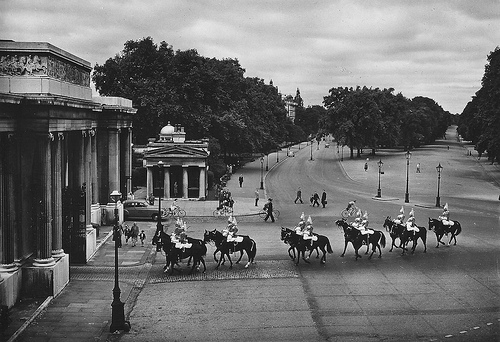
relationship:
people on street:
[287, 201, 454, 238] [16, 134, 498, 340]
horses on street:
[154, 216, 461, 271] [16, 134, 498, 340]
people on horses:
[287, 201, 454, 238] [154, 216, 461, 271]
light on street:
[374, 160, 384, 198] [324, 112, 497, 272]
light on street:
[402, 147, 412, 203] [324, 112, 497, 272]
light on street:
[432, 161, 443, 208] [324, 112, 497, 272]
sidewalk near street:
[14, 218, 163, 340] [189, 286, 438, 326]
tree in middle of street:
[93, 36, 500, 187] [181, 281, 423, 340]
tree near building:
[93, 36, 500, 187] [0, 27, 152, 272]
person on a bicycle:
[264, 199, 274, 219] [164, 207, 187, 218]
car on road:
[123, 199, 167, 221] [340, 268, 430, 324]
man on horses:
[170, 215, 189, 245] [269, 218, 337, 268]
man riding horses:
[170, 215, 189, 245] [269, 218, 337, 268]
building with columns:
[1, 38, 134, 308] [4, 127, 134, 272]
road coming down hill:
[266, 136, 392, 205] [107, 119, 497, 212]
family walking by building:
[114, 222, 146, 245] [1, 38, 134, 308]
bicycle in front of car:
[165, 197, 189, 219] [120, 195, 167, 222]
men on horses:
[291, 210, 320, 240] [429, 203, 466, 244]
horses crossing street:
[152, 229, 207, 276] [217, 281, 459, 331]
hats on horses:
[388, 195, 425, 217] [236, 214, 443, 288]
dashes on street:
[440, 323, 492, 338] [370, 257, 495, 340]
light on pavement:
[83, 113, 146, 170] [151, 284, 314, 340]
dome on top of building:
[159, 119, 174, 140] [135, 119, 211, 197]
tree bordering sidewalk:
[89, 36, 227, 186] [19, 85, 351, 340]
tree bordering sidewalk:
[93, 36, 500, 187] [19, 85, 351, 340]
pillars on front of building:
[16, 128, 98, 255] [1, 35, 108, 289]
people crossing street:
[307, 185, 334, 210] [291, 162, 341, 187]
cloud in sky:
[0, 0, 500, 77] [2, 2, 499, 112]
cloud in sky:
[172, 24, 380, 76] [2, 2, 499, 112]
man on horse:
[442, 200, 452, 222] [426, 217, 461, 244]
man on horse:
[406, 207, 420, 238] [392, 218, 427, 261]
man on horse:
[380, 196, 421, 221] [321, 202, 378, 274]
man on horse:
[302, 215, 314, 246] [284, 230, 332, 264]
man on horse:
[228, 216, 237, 238] [204, 227, 258, 269]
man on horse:
[302, 215, 313, 237] [282, 229, 333, 263]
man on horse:
[356, 210, 369, 232] [344, 223, 386, 259]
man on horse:
[406, 207, 420, 238] [387, 222, 426, 253]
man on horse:
[442, 200, 452, 222] [427, 216, 462, 247]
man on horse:
[170, 215, 189, 245] [154, 234, 209, 276]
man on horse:
[170, 215, 189, 245] [146, 222, 210, 275]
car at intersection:
[121, 192, 168, 220] [171, 204, 284, 243]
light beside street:
[432, 161, 443, 208] [265, 138, 499, 340]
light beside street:
[404, 150, 412, 203] [265, 138, 499, 340]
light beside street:
[375, 158, 384, 198] [265, 138, 499, 340]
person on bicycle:
[291, 187, 303, 204] [337, 198, 362, 220]